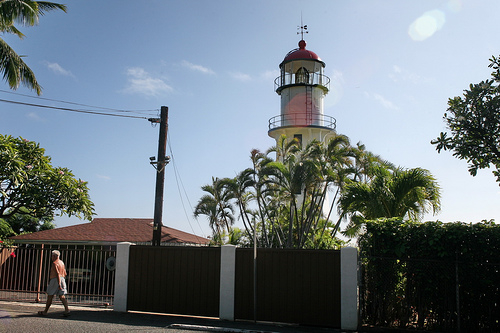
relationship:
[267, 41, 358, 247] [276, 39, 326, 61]
lighthouse with roof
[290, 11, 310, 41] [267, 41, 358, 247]
weather vane on lighthouse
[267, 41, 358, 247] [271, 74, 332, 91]
lighthouse has balcony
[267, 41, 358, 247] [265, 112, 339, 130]
lighthouse has railing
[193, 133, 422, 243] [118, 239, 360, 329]
palm trees behind wall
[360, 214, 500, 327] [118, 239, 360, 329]
hedge next to wall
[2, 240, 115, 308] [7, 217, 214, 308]
gate in front of building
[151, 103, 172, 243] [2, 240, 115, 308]
pole behind gate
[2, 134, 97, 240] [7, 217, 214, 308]
tree in front of building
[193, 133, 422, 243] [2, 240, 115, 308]
palm trees behind gate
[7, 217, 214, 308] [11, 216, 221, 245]
building has roof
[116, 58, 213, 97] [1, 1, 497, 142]
clouds are in sky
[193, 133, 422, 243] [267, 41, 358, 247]
palm trees in front of lighthouse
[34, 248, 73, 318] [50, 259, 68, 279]
person wearing shirt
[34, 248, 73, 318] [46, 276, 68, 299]
person wearing shorts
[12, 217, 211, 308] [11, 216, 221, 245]
building with roof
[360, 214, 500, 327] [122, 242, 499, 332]
bush next to fence